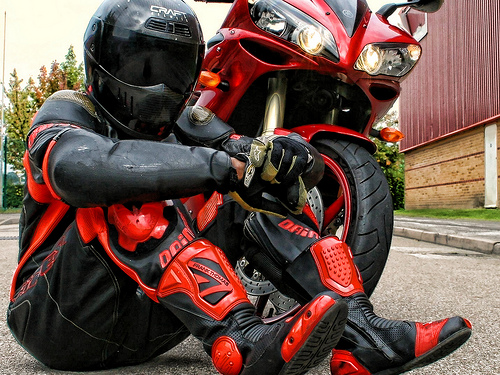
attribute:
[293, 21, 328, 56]
light — on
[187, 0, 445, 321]
motorcycle — red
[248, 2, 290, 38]
headlight — white, on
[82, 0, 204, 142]
helmet — black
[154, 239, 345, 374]
boots — black, red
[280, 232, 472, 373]
boots — black, red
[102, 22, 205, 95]
goggles — dark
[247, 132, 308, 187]
glove — black, green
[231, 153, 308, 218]
glove — black, green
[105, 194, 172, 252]
knee pad — red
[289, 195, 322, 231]
knee pad — red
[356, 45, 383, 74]
headlight — on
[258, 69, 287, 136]
bar — gold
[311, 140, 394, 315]
tire — black